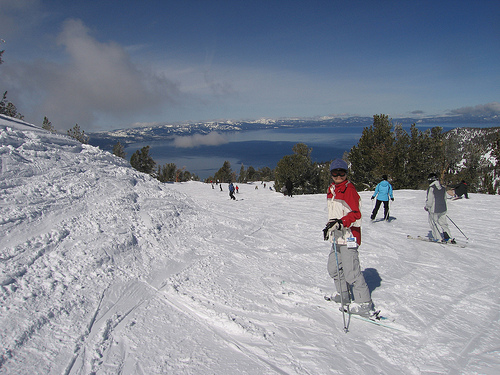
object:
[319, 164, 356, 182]
goggles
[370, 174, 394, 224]
woman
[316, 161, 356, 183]
woman goggles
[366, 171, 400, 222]
person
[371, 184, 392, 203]
jacket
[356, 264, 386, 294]
shadow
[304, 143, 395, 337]
man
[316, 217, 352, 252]
hand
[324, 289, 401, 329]
ski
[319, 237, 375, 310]
grey pants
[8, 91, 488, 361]
hill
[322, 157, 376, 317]
person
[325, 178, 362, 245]
jacket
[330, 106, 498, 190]
trees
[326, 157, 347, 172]
hat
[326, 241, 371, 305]
pants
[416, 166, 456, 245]
man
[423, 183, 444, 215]
jacket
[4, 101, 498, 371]
snow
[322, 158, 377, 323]
woman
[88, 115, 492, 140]
mountains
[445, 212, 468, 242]
snow pole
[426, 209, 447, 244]
snow pole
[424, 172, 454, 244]
person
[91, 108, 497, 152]
background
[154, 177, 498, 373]
field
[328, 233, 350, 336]
ski poles